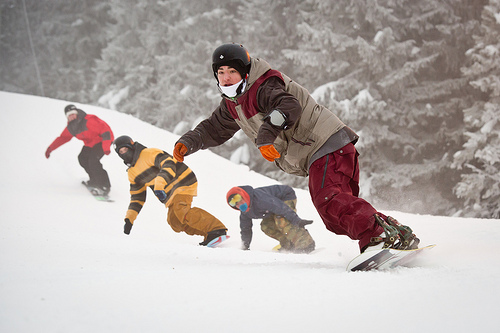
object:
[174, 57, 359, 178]
coat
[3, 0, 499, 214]
trees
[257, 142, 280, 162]
glove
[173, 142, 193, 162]
glove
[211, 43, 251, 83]
cap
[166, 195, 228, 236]
orange pants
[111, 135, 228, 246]
boy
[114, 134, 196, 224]
brown hood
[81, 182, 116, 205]
snow board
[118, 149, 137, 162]
mask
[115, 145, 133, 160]
face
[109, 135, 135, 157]
cap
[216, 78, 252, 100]
scarf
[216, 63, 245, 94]
face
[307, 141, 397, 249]
burgundy pants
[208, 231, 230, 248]
snowboard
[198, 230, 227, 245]
foot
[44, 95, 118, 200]
man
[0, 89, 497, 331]
hill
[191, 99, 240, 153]
arm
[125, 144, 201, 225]
coat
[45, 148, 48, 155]
glove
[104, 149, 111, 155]
glove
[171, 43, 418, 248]
boy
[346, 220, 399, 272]
shoe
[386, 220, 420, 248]
shoe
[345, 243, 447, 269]
snowboard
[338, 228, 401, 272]
man's feet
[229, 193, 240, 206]
goggle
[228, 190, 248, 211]
face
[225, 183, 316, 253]
man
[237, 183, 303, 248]
coat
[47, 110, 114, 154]
coat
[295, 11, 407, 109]
snow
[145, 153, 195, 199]
stripes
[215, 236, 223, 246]
design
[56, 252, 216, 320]
snow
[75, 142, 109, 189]
pants